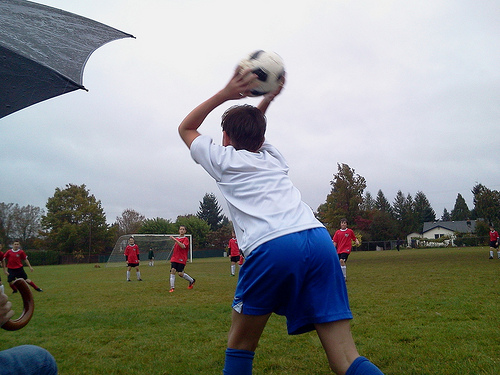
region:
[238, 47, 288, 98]
Black and white soccer ball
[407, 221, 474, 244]
A white house with two visible windows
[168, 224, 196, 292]
Boy in soccer uniform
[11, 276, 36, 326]
Brown umbrella handle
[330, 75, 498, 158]
Thick clouds in the sky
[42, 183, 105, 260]
Tall full tree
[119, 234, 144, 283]
Boy in a red shirt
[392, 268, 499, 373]
Shortly cut green grass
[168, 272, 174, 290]
White knee high sock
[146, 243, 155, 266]
Kid wearing black clothing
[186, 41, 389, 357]
the boy is holding the bowl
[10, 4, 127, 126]
the umbrella is wet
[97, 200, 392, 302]
the kids are playing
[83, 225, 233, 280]
the shirts are red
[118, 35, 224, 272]
the sky is cloudy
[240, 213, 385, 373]
the shorts is blue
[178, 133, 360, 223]
the shirt is white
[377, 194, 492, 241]
the roof is gray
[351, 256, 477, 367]
grass on the ground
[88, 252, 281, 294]
kids are wearing socks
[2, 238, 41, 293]
a child playing soccer on a field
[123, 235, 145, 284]
a child playing soccer on a field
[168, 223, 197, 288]
a child playing soccer on a field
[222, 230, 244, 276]
a child playing soccer on a field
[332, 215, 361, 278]
a child playing soccer on a field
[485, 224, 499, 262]
a child playing soccer on a field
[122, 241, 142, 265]
a red and white soccer jersey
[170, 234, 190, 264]
a red and white soccer jersey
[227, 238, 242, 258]
a red and white soccer jersey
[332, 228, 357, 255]
a red and white soccer jersey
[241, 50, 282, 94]
the soccer ball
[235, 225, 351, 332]
the blue soccer shorts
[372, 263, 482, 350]
the short green grass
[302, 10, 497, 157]
the over cast sky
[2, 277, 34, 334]
the wooden umbrella handle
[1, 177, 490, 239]
the trees all lined up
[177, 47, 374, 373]
the boy holding the soccer ball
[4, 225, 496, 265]
the soccer players in red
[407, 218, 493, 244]
the house in the bac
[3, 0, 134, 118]
the top of the black umbrella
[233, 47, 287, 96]
Soccer ball in motion.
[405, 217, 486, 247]
Home near the soccer fields.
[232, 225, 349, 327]
Soccer player wearing blue shorts.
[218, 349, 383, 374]
Soccer player wearing blue socks.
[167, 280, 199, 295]
Soccer player wearing red soccer shoes.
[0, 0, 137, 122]
Black, wet umbrella keeping someone dry.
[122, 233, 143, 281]
Soccer player wearing red shirt and black shorts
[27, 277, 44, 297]
Soccer player wearing red and black socks.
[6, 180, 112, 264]
Trees at the edge of the field.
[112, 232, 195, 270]
Good -sized goalie screen.